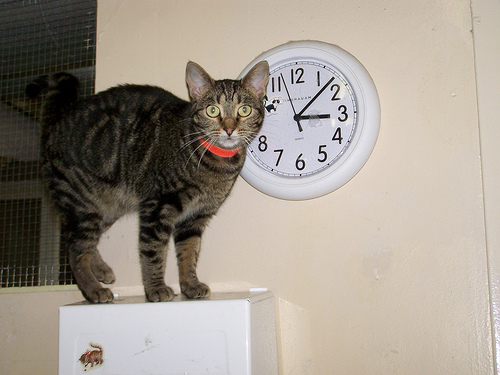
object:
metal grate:
[2, 10, 87, 270]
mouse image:
[78, 342, 105, 371]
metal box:
[53, 286, 280, 375]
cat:
[37, 59, 270, 305]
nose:
[222, 118, 238, 136]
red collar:
[199, 139, 240, 159]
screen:
[4, 6, 101, 299]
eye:
[206, 105, 221, 119]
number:
[290, 68, 305, 85]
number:
[317, 71, 321, 87]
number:
[330, 84, 341, 101]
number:
[295, 153, 306, 171]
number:
[331, 127, 343, 145]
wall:
[0, 2, 500, 373]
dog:
[265, 97, 282, 117]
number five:
[317, 144, 328, 162]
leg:
[136, 199, 175, 303]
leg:
[174, 213, 213, 300]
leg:
[60, 210, 115, 304]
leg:
[85, 223, 116, 285]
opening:
[2, 6, 103, 290]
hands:
[279, 72, 303, 132]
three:
[337, 104, 349, 122]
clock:
[230, 38, 380, 201]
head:
[184, 60, 270, 149]